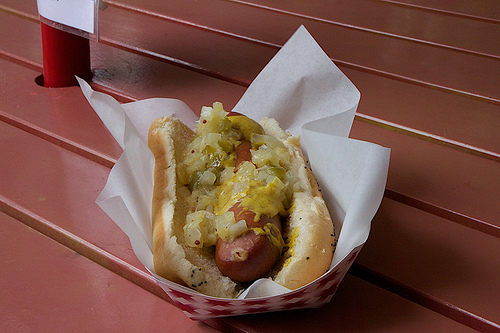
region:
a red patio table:
[7, 82, 89, 329]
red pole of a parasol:
[24, 34, 76, 85]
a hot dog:
[103, 93, 345, 286]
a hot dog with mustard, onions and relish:
[147, 105, 323, 283]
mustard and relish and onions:
[185, 112, 241, 232]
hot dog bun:
[146, 115, 202, 285]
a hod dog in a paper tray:
[91, 89, 409, 326]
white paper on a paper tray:
[83, 66, 163, 295]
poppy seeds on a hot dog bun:
[183, 257, 215, 298]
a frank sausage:
[227, 127, 270, 279]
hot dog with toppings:
[76, 41, 381, 328]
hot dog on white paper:
[61, 65, 436, 312]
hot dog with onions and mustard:
[149, 86, 356, 313]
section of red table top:
[395, 6, 498, 319]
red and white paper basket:
[151, 258, 358, 325]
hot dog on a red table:
[59, 56, 441, 331]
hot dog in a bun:
[128, 78, 345, 331]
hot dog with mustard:
[99, 41, 411, 310]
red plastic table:
[406, 18, 492, 326]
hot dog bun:
[281, 126, 353, 300]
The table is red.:
[370, 13, 497, 130]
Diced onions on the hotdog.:
[181, 181, 241, 250]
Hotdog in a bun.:
[211, 112, 281, 275]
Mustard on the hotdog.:
[216, 159, 289, 247]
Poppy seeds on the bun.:
[175, 265, 218, 295]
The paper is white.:
[108, 169, 150, 244]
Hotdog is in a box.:
[156, 105, 348, 325]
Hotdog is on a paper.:
[150, 100, 346, 282]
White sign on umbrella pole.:
[36, 0, 110, 42]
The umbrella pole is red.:
[29, 20, 101, 87]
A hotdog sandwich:
[165, 94, 299, 266]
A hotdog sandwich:
[147, 136, 261, 284]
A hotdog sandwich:
[200, 142, 342, 285]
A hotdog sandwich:
[174, 202, 321, 325]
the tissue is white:
[352, 193, 366, 220]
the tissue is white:
[341, 205, 356, 248]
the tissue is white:
[352, 208, 364, 240]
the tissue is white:
[350, 191, 358, 219]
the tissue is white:
[342, 193, 353, 220]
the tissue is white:
[342, 201, 358, 231]